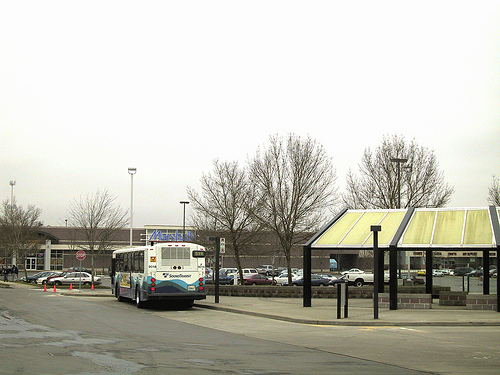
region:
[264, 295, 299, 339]
edge of a road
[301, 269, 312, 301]
part of a tand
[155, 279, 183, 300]
edge of a bus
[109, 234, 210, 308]
this is a bus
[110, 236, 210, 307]
the bus is parked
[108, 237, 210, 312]
the bus is long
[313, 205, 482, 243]
this is the roof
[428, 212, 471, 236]
the roof is glass like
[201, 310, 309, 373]
this is the road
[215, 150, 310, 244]
these are the trees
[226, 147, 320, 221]
the trees are dry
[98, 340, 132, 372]
the road is watery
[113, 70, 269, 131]
the sky is white in color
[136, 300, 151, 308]
part of a wheel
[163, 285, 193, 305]
edge of a bus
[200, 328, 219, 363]
part of a r0oad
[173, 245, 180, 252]
part of a window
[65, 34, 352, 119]
this is the sky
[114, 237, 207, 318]
this is a bus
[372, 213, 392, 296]
this is a pole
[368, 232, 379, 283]
the pole is black in color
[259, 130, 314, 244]
this is a tree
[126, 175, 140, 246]
the pole is white in color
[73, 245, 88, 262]
this is a signpost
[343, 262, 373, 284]
this is a car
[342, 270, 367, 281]
the car is white in color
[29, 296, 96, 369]
this is the road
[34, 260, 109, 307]
orange cones on the ground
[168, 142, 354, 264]
trees without any leaves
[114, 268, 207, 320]
blue trim on the bus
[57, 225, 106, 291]
a stop sign in the distance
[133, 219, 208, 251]
blue sign on building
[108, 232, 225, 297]
white and blue bus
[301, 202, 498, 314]
shelter at the bus stop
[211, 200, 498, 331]
bus stop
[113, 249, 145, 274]
black windows on the bus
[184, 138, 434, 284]
trees behind the bus stop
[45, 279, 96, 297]
orange cones on the sidewalk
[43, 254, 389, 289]
cars in the parking lot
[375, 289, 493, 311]
benches at the bus stop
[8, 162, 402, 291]
lights along the sidewalk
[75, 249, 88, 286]
red and white stop sign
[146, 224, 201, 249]
the sign is blue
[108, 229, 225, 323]
the bus is white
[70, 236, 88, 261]
the sign is red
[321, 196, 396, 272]
the roof is yellow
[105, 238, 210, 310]
blue and white transit bus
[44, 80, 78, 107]
white clouds in blue sky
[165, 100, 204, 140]
white clouds in blue sky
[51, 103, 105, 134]
white clouds in blue sky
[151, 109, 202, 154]
white clouds in blue sky